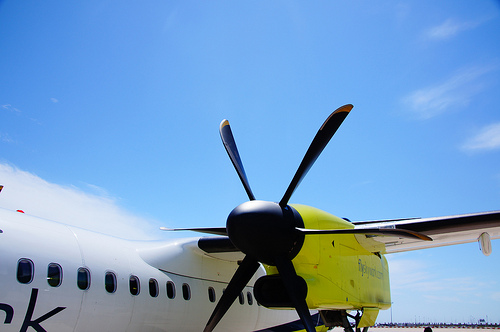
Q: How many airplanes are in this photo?
A: One.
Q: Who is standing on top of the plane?
A: No one.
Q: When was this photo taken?
A: Daytime.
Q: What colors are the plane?
A: White, yellow, black.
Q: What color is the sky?
A: Blue.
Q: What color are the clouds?
A: White.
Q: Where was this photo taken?
A: On an airfield.